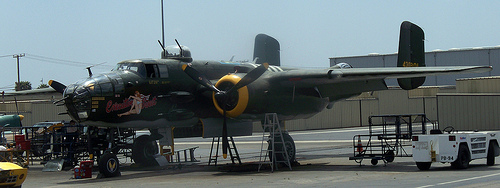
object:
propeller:
[180, 62, 272, 160]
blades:
[220, 110, 231, 160]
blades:
[178, 64, 224, 94]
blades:
[225, 62, 273, 95]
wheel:
[265, 132, 298, 167]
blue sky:
[0, 0, 500, 88]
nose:
[53, 73, 127, 130]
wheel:
[450, 143, 473, 170]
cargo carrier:
[349, 111, 438, 167]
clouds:
[0, 0, 500, 89]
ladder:
[223, 135, 245, 166]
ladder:
[255, 112, 280, 173]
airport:
[0, 120, 500, 187]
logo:
[103, 90, 161, 118]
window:
[155, 63, 170, 79]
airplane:
[46, 33, 492, 178]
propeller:
[47, 79, 68, 94]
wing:
[260, 65, 494, 88]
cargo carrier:
[410, 125, 500, 171]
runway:
[25, 121, 500, 188]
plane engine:
[210, 72, 333, 122]